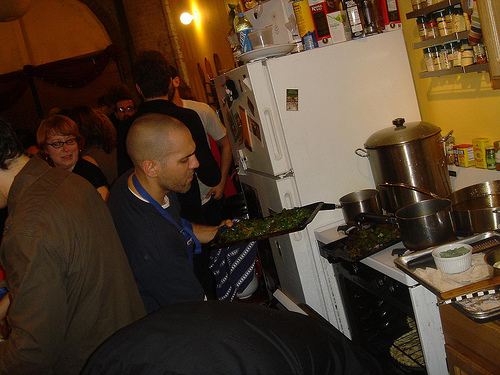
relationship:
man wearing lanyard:
[108, 112, 235, 304] [129, 174, 204, 255]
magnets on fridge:
[219, 77, 258, 150] [227, 49, 419, 343]